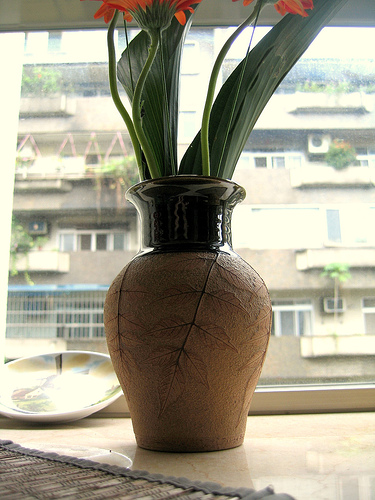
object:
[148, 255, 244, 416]
pattern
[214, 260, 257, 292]
imprints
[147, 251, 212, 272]
imprints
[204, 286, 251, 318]
imprints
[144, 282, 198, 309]
imprints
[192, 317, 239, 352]
imprints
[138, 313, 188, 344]
imprints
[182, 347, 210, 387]
imprints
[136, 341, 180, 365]
imprints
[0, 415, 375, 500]
ground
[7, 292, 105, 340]
fence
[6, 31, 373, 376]
building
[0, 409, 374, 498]
tabletop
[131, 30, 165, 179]
stem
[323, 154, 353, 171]
hanging basket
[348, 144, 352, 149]
flowers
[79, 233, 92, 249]
doors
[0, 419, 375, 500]
table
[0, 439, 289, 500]
mat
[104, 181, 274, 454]
beige vase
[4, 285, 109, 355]
balcony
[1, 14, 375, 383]
window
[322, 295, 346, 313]
air condition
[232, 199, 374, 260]
apartment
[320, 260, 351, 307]
plant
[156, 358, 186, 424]
leaf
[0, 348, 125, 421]
plate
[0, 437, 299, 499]
trim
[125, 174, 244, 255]
vase top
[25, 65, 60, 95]
plant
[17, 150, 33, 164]
plant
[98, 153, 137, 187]
plant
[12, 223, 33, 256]
plant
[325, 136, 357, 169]
plant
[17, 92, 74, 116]
balcony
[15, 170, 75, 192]
balcony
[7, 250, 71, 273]
balcony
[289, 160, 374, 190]
balcony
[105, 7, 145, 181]
stem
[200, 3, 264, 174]
stem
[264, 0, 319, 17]
flower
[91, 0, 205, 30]
flower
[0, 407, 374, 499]
surface